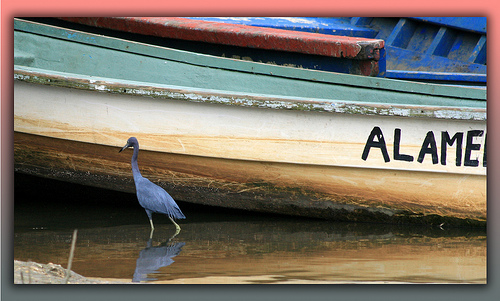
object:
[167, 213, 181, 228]
leg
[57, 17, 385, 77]
rust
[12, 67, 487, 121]
crackled paint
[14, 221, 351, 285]
water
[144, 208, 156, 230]
bird legs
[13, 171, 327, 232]
shadow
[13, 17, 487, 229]
boat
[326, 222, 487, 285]
water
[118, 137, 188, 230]
bird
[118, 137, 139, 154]
head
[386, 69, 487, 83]
edge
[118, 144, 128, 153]
beak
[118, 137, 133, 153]
face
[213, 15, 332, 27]
rust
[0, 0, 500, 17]
border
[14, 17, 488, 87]
blue boat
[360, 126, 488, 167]
name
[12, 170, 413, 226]
water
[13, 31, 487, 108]
paint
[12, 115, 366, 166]
water stain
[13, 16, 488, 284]
photo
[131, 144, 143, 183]
neck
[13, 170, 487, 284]
river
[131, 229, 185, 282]
reflection